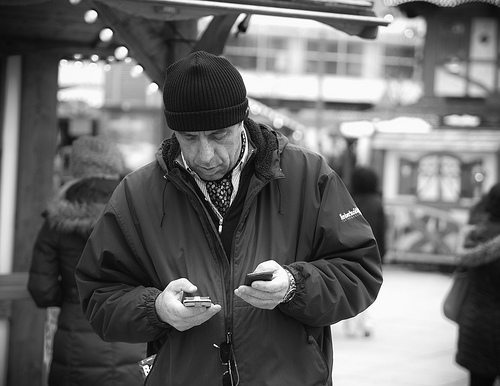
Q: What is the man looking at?
A: Phone.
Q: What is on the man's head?
A: Hat.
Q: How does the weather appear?
A: Chilly.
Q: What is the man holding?
A: Two cell phones.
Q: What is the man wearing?
A: Heavy jacket.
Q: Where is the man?
A: City.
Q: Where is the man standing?
A: Sidewalk.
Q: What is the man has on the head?
A: Hat.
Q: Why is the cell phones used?
A: Communicate.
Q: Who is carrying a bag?
A: A person.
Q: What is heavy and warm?
A: A winter jacket.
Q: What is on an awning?
A: Lights.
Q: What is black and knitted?
A: A hat.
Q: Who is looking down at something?
A: A man.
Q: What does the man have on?
A: A jacket.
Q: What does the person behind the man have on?
A: A jacket.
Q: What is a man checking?
A: Cell phone.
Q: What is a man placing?
A: A call.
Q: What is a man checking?
A: Messages.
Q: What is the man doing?
A: Looking at his phone.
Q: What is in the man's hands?
A: Two cell phones.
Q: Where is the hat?
A: On the man's head.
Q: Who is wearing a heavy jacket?
A: A man.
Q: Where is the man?
A: In a city.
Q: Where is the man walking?
A: On a sidewalk.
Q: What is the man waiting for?
A: A bus.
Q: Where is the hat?
A: On the man's head.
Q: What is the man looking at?
A: A cell phone.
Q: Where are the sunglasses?
A: Hanging on the zipper.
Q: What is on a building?
A: Windows.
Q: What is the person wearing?
A: Winter jacket.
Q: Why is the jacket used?
A: Cover.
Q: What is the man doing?
A: Looking at cell phone.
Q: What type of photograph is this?
A: Black and white.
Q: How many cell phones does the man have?
A: 2.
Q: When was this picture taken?
A: Daytime.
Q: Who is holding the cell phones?
A: Man.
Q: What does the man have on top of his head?
A: Hat.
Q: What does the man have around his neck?
A: Scarf.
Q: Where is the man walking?
A: Sidewalk.